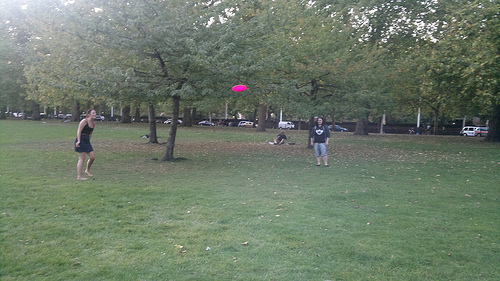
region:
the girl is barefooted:
[73, 165, 102, 187]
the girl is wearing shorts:
[70, 135, 97, 161]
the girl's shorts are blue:
[69, 128, 99, 162]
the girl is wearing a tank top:
[71, 114, 101, 150]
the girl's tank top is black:
[78, 122, 95, 137]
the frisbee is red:
[221, 76, 255, 113]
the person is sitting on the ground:
[257, 120, 296, 151]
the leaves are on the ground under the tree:
[51, 125, 487, 192]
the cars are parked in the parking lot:
[8, 106, 496, 145]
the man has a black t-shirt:
[310, 123, 327, 145]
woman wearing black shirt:
[63, 100, 108, 180]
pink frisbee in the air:
[225, 74, 252, 94]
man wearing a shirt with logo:
[301, 112, 336, 176]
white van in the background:
[458, 123, 476, 134]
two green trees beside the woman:
[107, 11, 201, 171]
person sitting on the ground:
[267, 128, 294, 163]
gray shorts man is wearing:
[310, 139, 328, 154]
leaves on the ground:
[192, 126, 239, 170]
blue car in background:
[329, 121, 349, 133]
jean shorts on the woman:
[72, 137, 97, 154]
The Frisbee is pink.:
[231, 82, 251, 93]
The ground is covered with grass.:
[0, 117, 499, 279]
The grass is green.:
[1, 118, 497, 278]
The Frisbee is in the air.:
[228, 83, 248, 95]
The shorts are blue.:
[66, 135, 103, 155]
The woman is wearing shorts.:
[73, 133, 95, 153]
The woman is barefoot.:
[73, 165, 98, 180]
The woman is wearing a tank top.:
[77, 118, 97, 137]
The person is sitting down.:
[270, 128, 290, 145]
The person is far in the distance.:
[271, 128, 291, 144]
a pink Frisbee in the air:
[230, 84, 247, 91]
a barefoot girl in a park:
[73, 108, 98, 180]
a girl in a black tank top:
[73, 108, 98, 181]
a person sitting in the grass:
[271, 130, 287, 145]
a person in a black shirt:
[310, 115, 330, 165]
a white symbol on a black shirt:
[314, 128, 323, 134]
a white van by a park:
[277, 120, 295, 129]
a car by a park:
[196, 118, 215, 125]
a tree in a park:
[19, 0, 284, 161]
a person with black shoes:
[309, 115, 330, 166]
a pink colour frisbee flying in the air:
[231, 80, 248, 95]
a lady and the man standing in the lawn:
[58, 104, 360, 183]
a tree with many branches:
[133, 31, 197, 181]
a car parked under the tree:
[455, 120, 495, 139]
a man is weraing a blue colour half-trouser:
[311, 140, 329, 158]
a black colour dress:
[74, 115, 96, 162]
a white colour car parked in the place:
[458, 123, 486, 141]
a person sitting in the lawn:
[272, 125, 292, 152]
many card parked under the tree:
[10, 108, 76, 120]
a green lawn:
[64, 205, 437, 261]